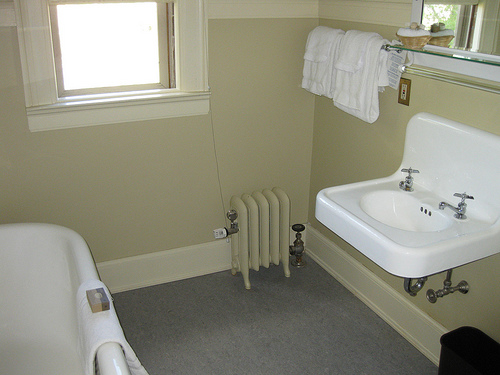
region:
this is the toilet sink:
[319, 125, 485, 265]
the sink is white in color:
[360, 145, 477, 245]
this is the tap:
[438, 186, 473, 219]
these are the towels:
[298, 25, 388, 108]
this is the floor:
[301, 285, 346, 337]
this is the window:
[51, 7, 169, 87]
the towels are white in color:
[303, 29, 382, 102]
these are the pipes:
[403, 275, 469, 301]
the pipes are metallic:
[400, 274, 466, 305]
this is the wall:
[109, 135, 186, 237]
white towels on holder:
[287, 14, 406, 124]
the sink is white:
[322, 158, 492, 283]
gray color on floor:
[161, 284, 318, 337]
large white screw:
[205, 219, 246, 252]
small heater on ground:
[226, 188, 313, 281]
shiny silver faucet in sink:
[436, 191, 473, 223]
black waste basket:
[433, 312, 488, 363]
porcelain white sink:
[314, 125, 489, 272]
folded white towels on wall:
[288, 22, 406, 117]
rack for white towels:
[375, 33, 411, 55]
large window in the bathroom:
[36, 32, 212, 107]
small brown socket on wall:
[393, 75, 415, 112]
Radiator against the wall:
[217, 186, 300, 292]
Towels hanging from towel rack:
[299, 25, 399, 125]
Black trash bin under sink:
[436, 322, 498, 372]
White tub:
[0, 218, 130, 374]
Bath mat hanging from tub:
[74, 283, 145, 371]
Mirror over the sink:
[414, 0, 499, 58]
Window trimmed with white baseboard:
[10, 0, 215, 135]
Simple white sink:
[314, 108, 499, 302]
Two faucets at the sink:
[398, 161, 474, 225]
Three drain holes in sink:
[413, 201, 438, 218]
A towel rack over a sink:
[383, 39, 498, 72]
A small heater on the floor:
[224, 183, 292, 283]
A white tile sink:
[310, 111, 496, 278]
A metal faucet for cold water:
[438, 189, 475, 221]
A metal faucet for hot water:
[392, 165, 421, 192]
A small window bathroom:
[47, 1, 179, 99]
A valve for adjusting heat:
[290, 220, 307, 234]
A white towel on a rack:
[297, 20, 394, 121]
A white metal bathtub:
[1, 215, 133, 373]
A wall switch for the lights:
[395, 77, 410, 106]